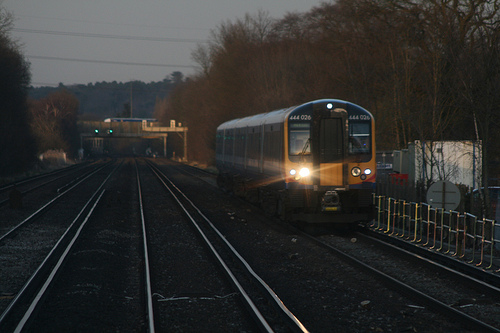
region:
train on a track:
[203, 90, 378, 224]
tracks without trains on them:
[39, 165, 223, 320]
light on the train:
[287, 164, 320, 179]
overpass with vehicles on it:
[70, 109, 192, 136]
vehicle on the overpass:
[104, 110, 166, 130]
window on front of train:
[288, 132, 311, 153]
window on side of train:
[218, 135, 279, 156]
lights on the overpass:
[91, 126, 123, 138]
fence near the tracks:
[384, 173, 468, 203]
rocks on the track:
[7, 239, 42, 251]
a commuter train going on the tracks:
[208, 106, 398, 239]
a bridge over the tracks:
[78, 103, 180, 158]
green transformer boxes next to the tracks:
[385, 131, 485, 216]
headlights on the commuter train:
[292, 160, 394, 181]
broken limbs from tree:
[160, 273, 245, 310]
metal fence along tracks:
[390, 186, 498, 274]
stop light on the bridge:
[87, 115, 120, 140]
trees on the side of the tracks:
[221, 35, 474, 131]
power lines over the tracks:
[10, 25, 216, 92]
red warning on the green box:
[388, 155, 416, 194]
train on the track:
[192, 70, 367, 214]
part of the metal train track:
[244, 300, 266, 330]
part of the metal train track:
[284, 303, 308, 327]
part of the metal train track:
[257, 275, 277, 297]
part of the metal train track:
[138, 298, 160, 328]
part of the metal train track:
[132, 238, 157, 265]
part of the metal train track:
[137, 244, 162, 270]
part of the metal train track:
[222, 234, 248, 262]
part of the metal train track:
[207, 218, 233, 246]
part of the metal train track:
[137, 214, 151, 229]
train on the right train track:
[217, 95, 374, 225]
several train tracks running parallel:
[2, 154, 498, 322]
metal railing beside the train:
[374, 193, 498, 272]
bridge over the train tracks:
[72, 118, 172, 157]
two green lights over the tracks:
[93, 129, 111, 133]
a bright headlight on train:
[290, 166, 311, 176]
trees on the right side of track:
[158, 7, 498, 166]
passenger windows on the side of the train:
[218, 135, 284, 164]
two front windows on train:
[290, 123, 371, 156]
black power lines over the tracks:
[12, 27, 207, 72]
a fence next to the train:
[380, 192, 495, 248]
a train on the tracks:
[205, 96, 375, 231]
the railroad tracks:
[32, 150, 282, 320]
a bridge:
[75, 105, 187, 165]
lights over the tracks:
[91, 121, 126, 141]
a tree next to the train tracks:
[192, 25, 487, 90]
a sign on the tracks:
[425, 175, 460, 211]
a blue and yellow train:
[201, 91, 383, 218]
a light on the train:
[298, 168, 312, 178]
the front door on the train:
[317, 116, 344, 190]